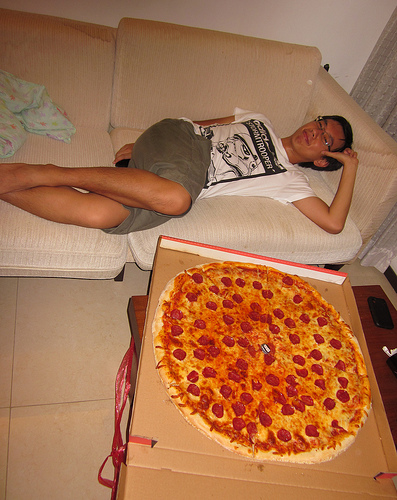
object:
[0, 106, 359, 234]
man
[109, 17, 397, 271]
couch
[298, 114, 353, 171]
hair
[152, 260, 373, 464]
pizza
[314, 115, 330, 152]
glasses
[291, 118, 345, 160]
face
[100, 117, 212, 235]
shorts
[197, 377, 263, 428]
cheese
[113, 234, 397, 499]
box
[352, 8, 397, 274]
curtain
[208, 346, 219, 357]
pepperoni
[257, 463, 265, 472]
stain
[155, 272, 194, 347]
crust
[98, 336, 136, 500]
lines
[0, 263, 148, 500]
floor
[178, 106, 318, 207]
clothing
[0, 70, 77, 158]
blankets